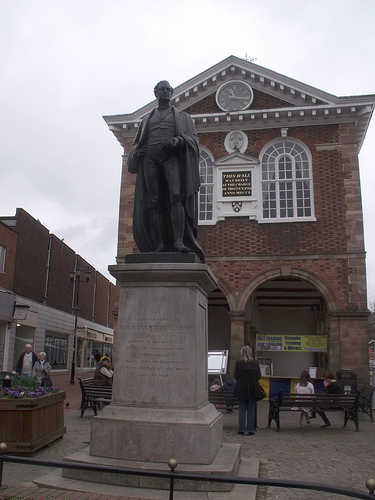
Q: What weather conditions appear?
A: It is overcast.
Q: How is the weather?
A: It is overcast.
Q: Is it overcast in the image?
A: Yes, it is overcast.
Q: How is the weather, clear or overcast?
A: It is overcast.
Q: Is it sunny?
A: No, it is overcast.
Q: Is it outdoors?
A: Yes, it is outdoors.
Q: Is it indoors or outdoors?
A: It is outdoors.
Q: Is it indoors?
A: No, it is outdoors.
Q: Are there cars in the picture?
A: No, there are no cars.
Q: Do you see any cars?
A: No, there are no cars.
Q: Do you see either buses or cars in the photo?
A: No, there are no cars or buses.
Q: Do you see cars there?
A: No, there are no cars.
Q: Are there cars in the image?
A: No, there are no cars.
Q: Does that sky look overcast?
A: Yes, the sky is overcast.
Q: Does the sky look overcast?
A: Yes, the sky is overcast.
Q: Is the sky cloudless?
A: No, the sky is overcast.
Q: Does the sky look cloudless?
A: No, the sky is overcast.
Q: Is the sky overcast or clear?
A: The sky is overcast.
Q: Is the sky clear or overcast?
A: The sky is overcast.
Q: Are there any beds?
A: Yes, there is a bed.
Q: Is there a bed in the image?
A: Yes, there is a bed.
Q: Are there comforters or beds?
A: Yes, there is a bed.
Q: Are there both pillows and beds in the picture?
A: No, there is a bed but no pillows.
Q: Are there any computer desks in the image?
A: No, there are no computer desks.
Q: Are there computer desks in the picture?
A: No, there are no computer desks.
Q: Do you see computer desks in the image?
A: No, there are no computer desks.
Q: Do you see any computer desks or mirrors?
A: No, there are no computer desks or mirrors.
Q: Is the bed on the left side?
A: Yes, the bed is on the left of the image.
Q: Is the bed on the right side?
A: No, the bed is on the left of the image.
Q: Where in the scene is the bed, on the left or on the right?
A: The bed is on the left of the image.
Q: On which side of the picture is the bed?
A: The bed is on the left of the image.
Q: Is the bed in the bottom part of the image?
A: Yes, the bed is in the bottom of the image.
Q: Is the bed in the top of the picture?
A: No, the bed is in the bottom of the image.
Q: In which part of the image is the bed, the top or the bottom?
A: The bed is in the bottom of the image.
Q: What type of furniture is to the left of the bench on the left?
A: The piece of furniture is a bed.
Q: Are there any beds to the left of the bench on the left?
A: Yes, there is a bed to the left of the bench.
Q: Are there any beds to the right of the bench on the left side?
A: No, the bed is to the left of the bench.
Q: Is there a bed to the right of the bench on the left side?
A: No, the bed is to the left of the bench.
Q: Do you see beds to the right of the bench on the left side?
A: No, the bed is to the left of the bench.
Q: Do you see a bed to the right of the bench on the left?
A: No, the bed is to the left of the bench.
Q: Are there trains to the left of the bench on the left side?
A: No, there is a bed to the left of the bench.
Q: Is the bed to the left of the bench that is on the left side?
A: Yes, the bed is to the left of the bench.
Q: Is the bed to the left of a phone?
A: No, the bed is to the left of the bench.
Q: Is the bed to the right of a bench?
A: No, the bed is to the left of a bench.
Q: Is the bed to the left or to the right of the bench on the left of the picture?
A: The bed is to the left of the bench.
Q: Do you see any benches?
A: Yes, there is a bench.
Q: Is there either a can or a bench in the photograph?
A: Yes, there is a bench.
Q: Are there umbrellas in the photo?
A: No, there are no umbrellas.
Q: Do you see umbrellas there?
A: No, there are no umbrellas.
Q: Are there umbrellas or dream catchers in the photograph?
A: No, there are no umbrellas or dream catchers.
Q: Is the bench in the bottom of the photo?
A: Yes, the bench is in the bottom of the image.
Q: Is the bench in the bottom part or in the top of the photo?
A: The bench is in the bottom of the image.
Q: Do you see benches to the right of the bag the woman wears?
A: Yes, there is a bench to the right of the purse.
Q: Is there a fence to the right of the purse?
A: No, there is a bench to the right of the purse.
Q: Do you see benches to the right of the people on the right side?
A: Yes, there is a bench to the right of the people.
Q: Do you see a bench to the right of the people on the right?
A: Yes, there is a bench to the right of the people.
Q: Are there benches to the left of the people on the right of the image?
A: No, the bench is to the right of the people.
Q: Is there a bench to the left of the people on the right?
A: No, the bench is to the right of the people.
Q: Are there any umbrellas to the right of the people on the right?
A: No, there is a bench to the right of the people.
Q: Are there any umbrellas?
A: No, there are no umbrellas.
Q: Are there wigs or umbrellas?
A: No, there are no umbrellas or wigs.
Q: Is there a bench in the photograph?
A: Yes, there is a bench.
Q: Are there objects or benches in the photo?
A: Yes, there is a bench.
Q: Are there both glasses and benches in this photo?
A: No, there is a bench but no glasses.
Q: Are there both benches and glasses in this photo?
A: No, there is a bench but no glasses.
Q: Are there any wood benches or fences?
A: Yes, there is a wood bench.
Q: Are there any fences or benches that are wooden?
A: Yes, the bench is wooden.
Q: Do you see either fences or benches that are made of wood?
A: Yes, the bench is made of wood.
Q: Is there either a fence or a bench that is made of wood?
A: Yes, the bench is made of wood.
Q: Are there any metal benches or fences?
A: Yes, there is a metal bench.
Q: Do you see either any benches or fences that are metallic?
A: Yes, the bench is metallic.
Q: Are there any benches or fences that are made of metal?
A: Yes, the bench is made of metal.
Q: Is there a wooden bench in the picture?
A: Yes, there is a wood bench.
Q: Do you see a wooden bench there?
A: Yes, there is a wood bench.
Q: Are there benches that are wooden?
A: Yes, there is a bench that is wooden.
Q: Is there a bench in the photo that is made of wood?
A: Yes, there is a bench that is made of wood.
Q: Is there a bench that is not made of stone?
A: Yes, there is a bench that is made of wood.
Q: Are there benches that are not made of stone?
A: Yes, there is a bench that is made of wood.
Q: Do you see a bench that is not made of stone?
A: Yes, there is a bench that is made of wood.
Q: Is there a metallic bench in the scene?
A: Yes, there is a metal bench.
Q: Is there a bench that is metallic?
A: Yes, there is a bench that is metallic.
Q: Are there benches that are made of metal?
A: Yes, there is a bench that is made of metal.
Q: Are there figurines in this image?
A: No, there are no figurines.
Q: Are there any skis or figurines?
A: No, there are no figurines or skis.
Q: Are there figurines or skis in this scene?
A: No, there are no figurines or skis.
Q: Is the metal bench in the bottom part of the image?
A: Yes, the bench is in the bottom of the image.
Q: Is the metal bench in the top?
A: No, the bench is in the bottom of the image.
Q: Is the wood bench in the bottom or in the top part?
A: The bench is in the bottom of the image.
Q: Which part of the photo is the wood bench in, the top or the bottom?
A: The bench is in the bottom of the image.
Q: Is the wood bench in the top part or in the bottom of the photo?
A: The bench is in the bottom of the image.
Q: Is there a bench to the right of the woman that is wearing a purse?
A: Yes, there is a bench to the right of the woman.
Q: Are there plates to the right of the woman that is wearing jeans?
A: No, there is a bench to the right of the woman.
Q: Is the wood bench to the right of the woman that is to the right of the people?
A: Yes, the bench is to the right of the woman.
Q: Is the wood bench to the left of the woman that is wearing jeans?
A: No, the bench is to the right of the woman.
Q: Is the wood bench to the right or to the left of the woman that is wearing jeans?
A: The bench is to the right of the woman.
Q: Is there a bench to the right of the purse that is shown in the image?
A: Yes, there is a bench to the right of the purse.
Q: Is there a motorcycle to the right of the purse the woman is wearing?
A: No, there is a bench to the right of the purse.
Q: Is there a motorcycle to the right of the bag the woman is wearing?
A: No, there is a bench to the right of the purse.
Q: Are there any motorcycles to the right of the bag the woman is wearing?
A: No, there is a bench to the right of the purse.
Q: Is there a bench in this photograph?
A: Yes, there is a bench.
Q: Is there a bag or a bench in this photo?
A: Yes, there is a bench.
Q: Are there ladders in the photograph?
A: No, there are no ladders.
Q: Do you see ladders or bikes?
A: No, there are no ladders or bikes.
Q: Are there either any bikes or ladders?
A: No, there are no ladders or bikes.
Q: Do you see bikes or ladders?
A: No, there are no ladders or bikes.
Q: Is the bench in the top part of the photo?
A: No, the bench is in the bottom of the image.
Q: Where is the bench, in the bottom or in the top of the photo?
A: The bench is in the bottom of the image.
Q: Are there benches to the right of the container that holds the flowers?
A: Yes, there is a bench to the right of the container.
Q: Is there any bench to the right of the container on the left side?
A: Yes, there is a bench to the right of the container.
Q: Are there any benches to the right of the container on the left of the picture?
A: Yes, there is a bench to the right of the container.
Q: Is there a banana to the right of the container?
A: No, there is a bench to the right of the container.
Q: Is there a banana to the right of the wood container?
A: No, there is a bench to the right of the container.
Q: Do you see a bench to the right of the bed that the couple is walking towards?
A: Yes, there is a bench to the right of the bed.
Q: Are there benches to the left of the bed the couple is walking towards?
A: No, the bench is to the right of the bed.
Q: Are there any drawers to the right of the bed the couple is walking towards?
A: No, there is a bench to the right of the bed.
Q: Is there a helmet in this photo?
A: No, there are no helmets.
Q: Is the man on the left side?
A: Yes, the man is on the left of the image.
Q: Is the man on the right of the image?
A: No, the man is on the left of the image.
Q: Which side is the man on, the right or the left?
A: The man is on the left of the image.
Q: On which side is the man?
A: The man is on the left of the image.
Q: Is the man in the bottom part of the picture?
A: Yes, the man is in the bottom of the image.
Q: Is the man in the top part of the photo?
A: No, the man is in the bottom of the image.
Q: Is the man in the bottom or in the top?
A: The man is in the bottom of the image.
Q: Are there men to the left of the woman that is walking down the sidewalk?
A: Yes, there is a man to the left of the woman.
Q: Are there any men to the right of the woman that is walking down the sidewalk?
A: No, the man is to the left of the woman.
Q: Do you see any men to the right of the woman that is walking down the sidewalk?
A: No, the man is to the left of the woman.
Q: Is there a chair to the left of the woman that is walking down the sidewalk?
A: No, there is a man to the left of the woman.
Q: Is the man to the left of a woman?
A: Yes, the man is to the left of a woman.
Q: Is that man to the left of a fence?
A: No, the man is to the left of a woman.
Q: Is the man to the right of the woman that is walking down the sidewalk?
A: No, the man is to the left of the woman.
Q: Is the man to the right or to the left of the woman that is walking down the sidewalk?
A: The man is to the left of the woman.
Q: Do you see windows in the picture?
A: Yes, there is a window.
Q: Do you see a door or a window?
A: Yes, there is a window.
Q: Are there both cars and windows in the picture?
A: No, there is a window but no cars.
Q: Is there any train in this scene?
A: No, there are no trains.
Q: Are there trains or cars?
A: No, there are no trains or cars.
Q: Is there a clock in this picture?
A: Yes, there is a clock.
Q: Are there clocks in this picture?
A: Yes, there is a clock.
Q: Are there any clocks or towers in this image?
A: Yes, there is a clock.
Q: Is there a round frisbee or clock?
A: Yes, there is a round clock.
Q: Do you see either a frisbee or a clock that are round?
A: Yes, the clock is round.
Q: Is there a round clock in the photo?
A: Yes, there is a round clock.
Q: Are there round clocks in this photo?
A: Yes, there is a round clock.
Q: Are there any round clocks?
A: Yes, there is a round clock.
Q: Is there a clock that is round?
A: Yes, there is a clock that is round.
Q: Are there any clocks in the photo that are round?
A: Yes, there is a clock that is round.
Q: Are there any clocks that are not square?
A: Yes, there is a round clock.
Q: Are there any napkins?
A: No, there are no napkins.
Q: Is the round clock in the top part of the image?
A: Yes, the clock is in the top of the image.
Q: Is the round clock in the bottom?
A: No, the clock is in the top of the image.